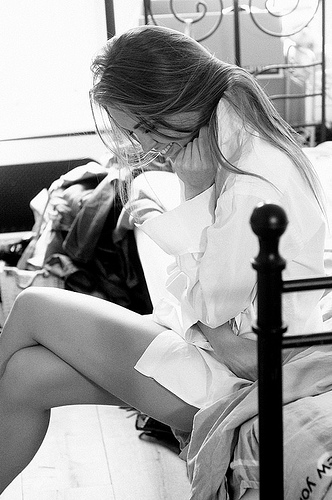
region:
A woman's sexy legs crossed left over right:
[0, 284, 201, 497]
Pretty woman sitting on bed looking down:
[85, 25, 326, 428]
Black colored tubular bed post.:
[242, 198, 291, 495]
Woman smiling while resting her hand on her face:
[88, 25, 233, 202]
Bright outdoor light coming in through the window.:
[0, 0, 149, 169]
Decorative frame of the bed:
[103, 0, 325, 185]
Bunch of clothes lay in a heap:
[0, 160, 131, 302]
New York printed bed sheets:
[185, 405, 330, 497]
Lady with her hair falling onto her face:
[85, 21, 236, 192]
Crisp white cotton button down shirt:
[131, 94, 331, 409]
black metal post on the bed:
[247, 194, 291, 499]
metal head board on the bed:
[143, 0, 329, 154]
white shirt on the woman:
[114, 85, 331, 405]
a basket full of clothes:
[28, 157, 143, 293]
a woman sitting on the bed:
[1, 22, 320, 497]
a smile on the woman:
[149, 138, 180, 163]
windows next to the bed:
[0, 0, 331, 167]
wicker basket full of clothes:
[0, 230, 73, 325]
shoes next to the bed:
[126, 405, 187, 449]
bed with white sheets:
[128, 136, 330, 496]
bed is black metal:
[251, 199, 327, 494]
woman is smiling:
[90, 18, 203, 166]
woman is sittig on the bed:
[0, 20, 326, 491]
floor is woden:
[0, 400, 175, 489]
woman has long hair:
[90, 19, 321, 202]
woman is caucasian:
[2, 28, 260, 499]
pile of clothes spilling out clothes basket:
[0, 156, 140, 314]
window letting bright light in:
[0, 0, 135, 128]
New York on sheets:
[276, 445, 318, 486]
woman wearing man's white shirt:
[116, 85, 317, 409]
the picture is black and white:
[7, 7, 322, 430]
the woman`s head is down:
[62, 18, 284, 193]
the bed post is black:
[224, 184, 306, 443]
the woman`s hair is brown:
[73, 18, 284, 170]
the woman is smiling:
[87, 87, 188, 166]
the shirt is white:
[112, 100, 323, 339]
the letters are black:
[277, 453, 331, 499]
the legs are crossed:
[5, 278, 184, 459]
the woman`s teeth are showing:
[140, 130, 184, 157]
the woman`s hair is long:
[76, 29, 325, 196]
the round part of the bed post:
[240, 198, 297, 268]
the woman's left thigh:
[21, 283, 210, 424]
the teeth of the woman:
[154, 139, 176, 157]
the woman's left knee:
[9, 279, 57, 343]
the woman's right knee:
[0, 341, 75, 418]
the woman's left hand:
[169, 126, 224, 195]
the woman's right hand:
[219, 324, 268, 380]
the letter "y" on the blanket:
[302, 469, 320, 496]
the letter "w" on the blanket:
[308, 459, 331, 480]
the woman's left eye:
[139, 115, 159, 135]